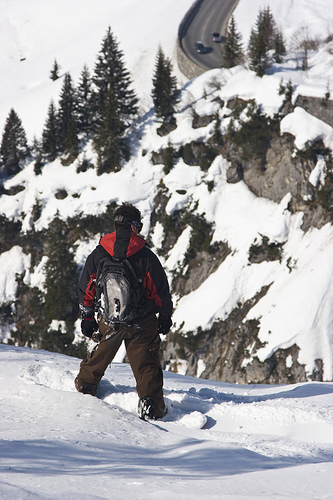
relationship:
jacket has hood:
[81, 230, 172, 334] [96, 230, 145, 262]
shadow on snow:
[173, 380, 329, 407] [3, 352, 329, 500]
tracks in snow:
[33, 356, 72, 398] [3, 352, 329, 500]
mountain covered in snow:
[2, 65, 330, 378] [21, 162, 298, 243]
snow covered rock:
[21, 162, 298, 243] [144, 132, 329, 243]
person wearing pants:
[76, 205, 174, 421] [77, 320, 167, 421]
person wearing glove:
[76, 205, 174, 421] [157, 313, 172, 332]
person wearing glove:
[76, 205, 174, 421] [79, 315, 98, 336]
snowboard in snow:
[63, 374, 209, 432] [3, 352, 329, 500]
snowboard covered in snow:
[63, 374, 209, 432] [3, 352, 329, 500]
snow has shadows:
[3, 352, 329, 500] [6, 436, 321, 478]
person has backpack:
[76, 205, 174, 421] [93, 259, 144, 326]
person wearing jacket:
[76, 205, 174, 421] [81, 230, 172, 334]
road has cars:
[178, 3, 242, 69] [193, 32, 223, 56]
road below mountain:
[178, 3, 242, 69] [2, 65, 330, 378]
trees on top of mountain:
[61, 26, 176, 155] [2, 65, 330, 378]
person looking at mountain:
[76, 205, 174, 421] [2, 65, 330, 378]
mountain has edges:
[2, 65, 330, 378] [151, 146, 279, 178]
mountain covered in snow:
[2, 65, 330, 378] [3, 352, 329, 500]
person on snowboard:
[76, 205, 174, 421] [63, 374, 209, 432]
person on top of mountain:
[76, 205, 174, 421] [2, 65, 330, 378]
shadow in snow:
[173, 380, 329, 407] [3, 352, 329, 500]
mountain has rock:
[2, 65, 330, 378] [144, 132, 329, 243]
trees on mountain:
[61, 26, 176, 155] [2, 65, 330, 378]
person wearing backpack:
[76, 205, 174, 421] [93, 259, 144, 326]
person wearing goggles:
[76, 205, 174, 421] [115, 212, 145, 231]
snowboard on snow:
[63, 374, 209, 432] [3, 352, 329, 500]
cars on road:
[193, 32, 223, 56] [178, 3, 242, 69]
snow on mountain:
[3, 352, 329, 500] [2, 65, 330, 378]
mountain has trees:
[2, 65, 330, 378] [61, 26, 176, 155]